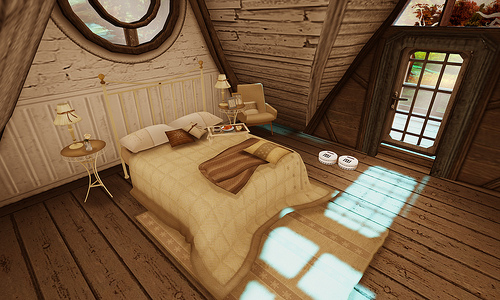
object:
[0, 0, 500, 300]
photograph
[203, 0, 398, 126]
wall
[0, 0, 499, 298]
bedroom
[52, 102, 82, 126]
lampshade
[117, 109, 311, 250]
bed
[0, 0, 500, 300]
room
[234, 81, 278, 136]
chair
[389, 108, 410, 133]
windows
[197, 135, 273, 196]
blanket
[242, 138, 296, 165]
pillow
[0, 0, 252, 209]
wall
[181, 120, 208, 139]
pillow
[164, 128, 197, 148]
pillow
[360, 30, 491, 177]
door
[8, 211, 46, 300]
line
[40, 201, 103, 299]
line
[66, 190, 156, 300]
line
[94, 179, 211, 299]
line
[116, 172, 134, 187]
line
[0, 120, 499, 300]
ground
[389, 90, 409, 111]
handle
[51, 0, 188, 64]
round shape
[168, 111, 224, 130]
pillows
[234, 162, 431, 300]
sunlight reflection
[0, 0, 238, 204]
bedroom wall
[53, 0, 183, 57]
window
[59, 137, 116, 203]
end table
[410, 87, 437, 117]
panes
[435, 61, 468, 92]
windows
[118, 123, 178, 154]
pillow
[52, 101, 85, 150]
lamp